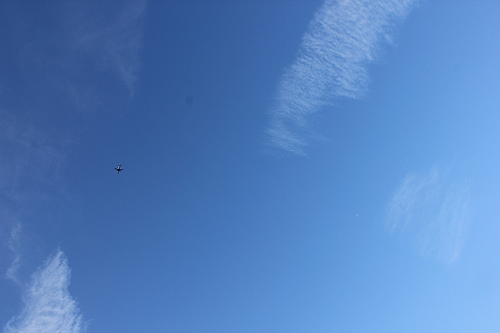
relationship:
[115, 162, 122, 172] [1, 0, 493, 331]
aircraft in sky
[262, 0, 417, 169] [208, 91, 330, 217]
cloud in sky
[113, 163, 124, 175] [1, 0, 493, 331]
aircraft flying in sky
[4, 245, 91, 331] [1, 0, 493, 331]
cloud in sky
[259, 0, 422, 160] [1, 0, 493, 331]
cloud in sky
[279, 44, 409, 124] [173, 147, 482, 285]
cloud in sky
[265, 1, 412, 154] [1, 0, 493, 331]
cloud in sky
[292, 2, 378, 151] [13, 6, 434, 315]
cloud in sky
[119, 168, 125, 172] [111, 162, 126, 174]
wing of plane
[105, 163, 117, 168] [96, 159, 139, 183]
wing of plane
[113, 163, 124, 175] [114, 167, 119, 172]
aircraft has wing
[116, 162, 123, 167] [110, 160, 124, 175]
wing on plane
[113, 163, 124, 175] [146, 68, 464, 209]
aircraft flying forward